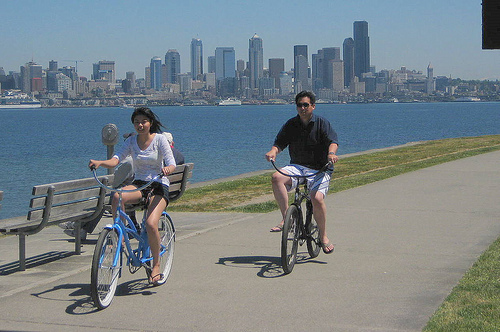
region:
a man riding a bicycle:
[265, 88, 337, 273]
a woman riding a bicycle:
[86, 105, 176, 313]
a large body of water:
[0, 101, 499, 218]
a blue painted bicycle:
[90, 163, 175, 307]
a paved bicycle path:
[0, 147, 499, 329]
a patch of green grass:
[423, 238, 498, 328]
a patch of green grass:
[148, 133, 498, 209]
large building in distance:
[353, 19, 369, 74]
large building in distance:
[343, 36, 354, 82]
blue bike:
[82, 208, 187, 298]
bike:
[271, 168, 333, 293]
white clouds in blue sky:
[404, 1, 454, 35]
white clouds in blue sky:
[207, 3, 244, 33]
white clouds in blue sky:
[115, 15, 162, 33]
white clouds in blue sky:
[67, 13, 131, 50]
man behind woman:
[265, 89, 335, 254]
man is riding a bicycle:
[263, 90, 338, 271]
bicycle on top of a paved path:
[2, 145, 496, 330]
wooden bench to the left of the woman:
[2, 173, 110, 270]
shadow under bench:
[2, 247, 80, 276]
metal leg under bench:
[17, 231, 27, 271]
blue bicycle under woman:
[86, 164, 176, 306]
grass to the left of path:
[171, 138, 499, 205]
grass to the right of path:
[419, 236, 499, 330]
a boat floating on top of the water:
[1, 86, 44, 109]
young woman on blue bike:
[57, 107, 184, 307]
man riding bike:
[267, 84, 343, 278]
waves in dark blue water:
[29, 124, 61, 161]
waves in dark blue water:
[245, 117, 280, 144]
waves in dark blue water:
[368, 110, 403, 135]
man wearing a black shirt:
[273, 96, 343, 162]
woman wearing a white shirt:
[118, 130, 168, 180]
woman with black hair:
[121, 102, 168, 141]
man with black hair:
[287, 87, 317, 129]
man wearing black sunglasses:
[289, 98, 310, 111]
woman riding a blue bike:
[82, 166, 196, 298]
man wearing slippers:
[316, 225, 336, 252]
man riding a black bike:
[252, 153, 338, 256]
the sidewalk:
[413, 197, 460, 239]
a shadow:
[221, 243, 274, 287]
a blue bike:
[89, 198, 189, 305]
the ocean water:
[19, 107, 65, 149]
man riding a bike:
[265, 90, 355, 255]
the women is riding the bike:
[101, 100, 188, 277]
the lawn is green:
[451, 297, 481, 329]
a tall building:
[345, 18, 379, 78]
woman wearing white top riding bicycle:
[89, 107, 176, 308]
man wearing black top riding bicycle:
[266, 91, 338, 272]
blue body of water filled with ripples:
[1, 100, 498, 218]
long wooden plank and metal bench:
[1, 162, 192, 268]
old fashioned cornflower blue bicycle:
[90, 162, 175, 307]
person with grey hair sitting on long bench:
[1, 132, 193, 269]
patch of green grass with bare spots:
[162, 134, 499, 210]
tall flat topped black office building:
[352, 21, 370, 80]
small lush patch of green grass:
[418, 239, 498, 329]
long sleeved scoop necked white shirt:
[113, 132, 175, 184]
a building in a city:
[342, 16, 381, 81]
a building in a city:
[334, 30, 355, 84]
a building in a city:
[322, 46, 347, 94]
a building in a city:
[290, 46, 312, 91]